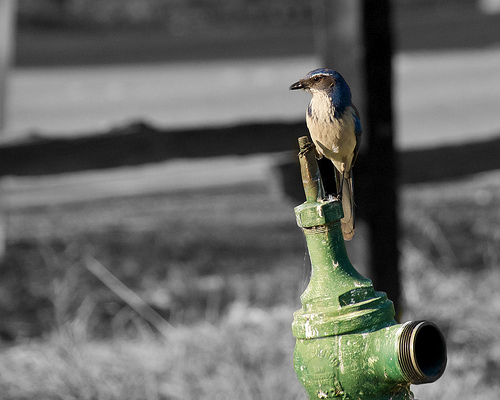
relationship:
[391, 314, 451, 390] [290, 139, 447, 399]
opening on fire hydrant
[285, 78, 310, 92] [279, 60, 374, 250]
beak of bird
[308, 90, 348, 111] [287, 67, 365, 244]
neck of bird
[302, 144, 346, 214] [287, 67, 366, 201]
legs of bird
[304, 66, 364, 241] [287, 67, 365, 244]
feathers of bird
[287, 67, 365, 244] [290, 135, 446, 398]
bird on fire hydrant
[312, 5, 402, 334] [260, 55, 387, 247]
pole behind bird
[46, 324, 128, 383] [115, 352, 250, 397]
grass on ground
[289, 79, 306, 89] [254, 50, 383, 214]
beak on bird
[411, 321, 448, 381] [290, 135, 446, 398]
opening on fire hydrant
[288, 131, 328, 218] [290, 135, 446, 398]
nozzle on fire hydrant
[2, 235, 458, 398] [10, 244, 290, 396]
snow on grass